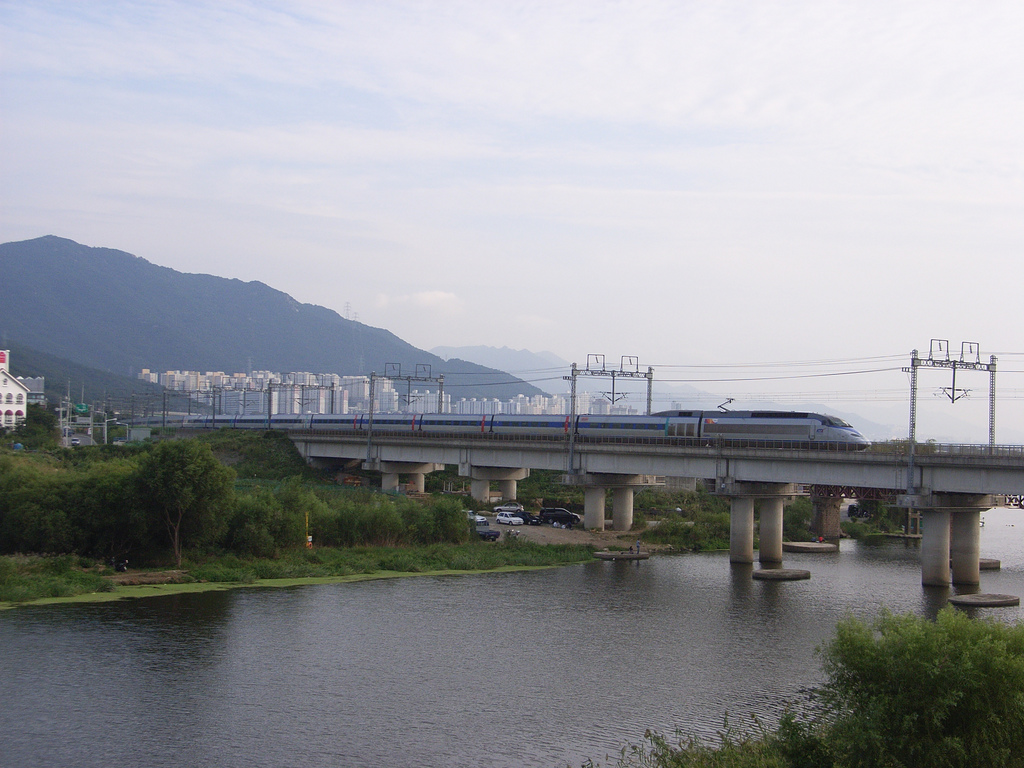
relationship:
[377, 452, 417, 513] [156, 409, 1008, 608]
pillar attached to bridge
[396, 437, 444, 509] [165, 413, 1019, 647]
pillar attached to bridge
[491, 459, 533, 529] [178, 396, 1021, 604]
pillar attached to bridge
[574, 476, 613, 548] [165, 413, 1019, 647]
pillar attached to bridge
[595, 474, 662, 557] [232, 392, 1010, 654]
pillar attached to bridge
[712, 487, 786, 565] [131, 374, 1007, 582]
pillar of bridge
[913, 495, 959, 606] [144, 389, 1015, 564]
pillar of bridge